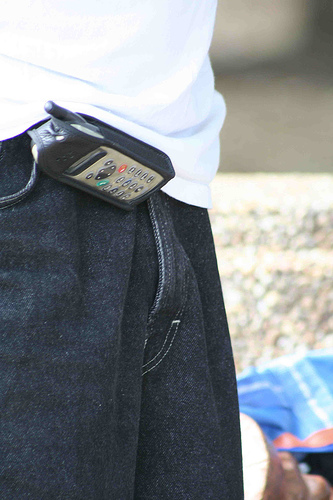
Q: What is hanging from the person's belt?
A: A cell phone.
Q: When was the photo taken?
A: Daytime.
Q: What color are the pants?
A: Blue.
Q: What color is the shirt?
A: White.